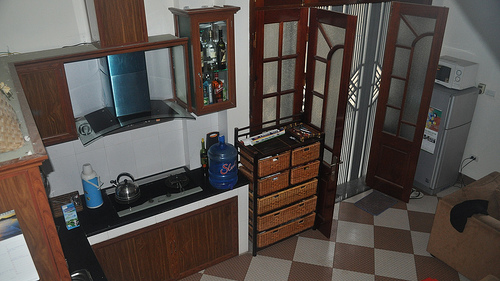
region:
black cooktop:
[108, 164, 203, 222]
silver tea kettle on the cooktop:
[111, 170, 139, 202]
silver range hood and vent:
[77, 58, 194, 143]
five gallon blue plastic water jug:
[207, 137, 237, 190]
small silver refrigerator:
[416, 80, 474, 192]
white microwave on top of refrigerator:
[434, 56, 478, 91]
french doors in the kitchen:
[260, 12, 449, 236]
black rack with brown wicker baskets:
[238, 118, 323, 248]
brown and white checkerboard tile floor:
[182, 191, 462, 279]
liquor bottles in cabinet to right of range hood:
[180, 5, 240, 115]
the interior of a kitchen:
[0, 0, 499, 280]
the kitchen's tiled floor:
[177, 182, 472, 279]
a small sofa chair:
[426, 170, 498, 279]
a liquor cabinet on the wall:
[167, 3, 240, 115]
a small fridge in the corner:
[412, 81, 480, 194]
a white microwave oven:
[435, 54, 480, 89]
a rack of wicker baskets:
[234, 110, 325, 256]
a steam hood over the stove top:
[73, 50, 196, 147]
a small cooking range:
[101, 164, 203, 221]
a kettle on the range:
[110, 171, 141, 202]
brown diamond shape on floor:
[336, 199, 375, 227]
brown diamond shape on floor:
[372, 186, 406, 209]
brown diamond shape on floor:
[302, 218, 341, 244]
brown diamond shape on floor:
[256, 233, 298, 260]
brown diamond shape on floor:
[204, 250, 256, 278]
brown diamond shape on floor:
[287, 260, 334, 276]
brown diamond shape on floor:
[332, 239, 376, 273]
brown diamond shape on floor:
[373, 224, 414, 254]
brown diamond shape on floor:
[404, 211, 434, 233]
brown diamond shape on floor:
[413, 253, 459, 278]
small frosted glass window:
[264, 25, 280, 60]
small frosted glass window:
[281, 21, 296, 55]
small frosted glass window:
[262, 59, 277, 94]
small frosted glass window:
[279, 60, 294, 90]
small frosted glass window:
[259, 96, 276, 120]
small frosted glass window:
[278, 93, 291, 115]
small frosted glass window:
[309, 93, 319, 127]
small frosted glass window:
[308, 58, 323, 94]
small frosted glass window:
[315, 28, 330, 58]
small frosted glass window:
[379, 107, 396, 136]